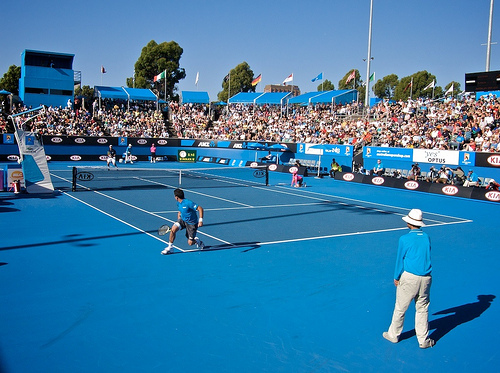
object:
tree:
[388, 70, 442, 107]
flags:
[308, 72, 325, 94]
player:
[103, 143, 118, 172]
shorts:
[105, 157, 116, 164]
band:
[405, 214, 423, 222]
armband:
[194, 216, 203, 224]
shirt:
[391, 229, 432, 283]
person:
[148, 140, 159, 164]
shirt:
[149, 145, 157, 153]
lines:
[180, 165, 472, 254]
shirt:
[175, 200, 201, 228]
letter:
[425, 157, 432, 164]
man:
[378, 206, 436, 349]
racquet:
[155, 223, 180, 238]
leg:
[166, 219, 184, 248]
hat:
[400, 205, 427, 227]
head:
[401, 208, 427, 229]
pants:
[386, 270, 433, 346]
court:
[0, 159, 499, 371]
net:
[68, 163, 270, 191]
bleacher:
[0, 49, 499, 205]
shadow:
[396, 294, 496, 345]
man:
[156, 187, 206, 255]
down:
[156, 219, 203, 255]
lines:
[54, 185, 187, 254]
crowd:
[0, 91, 499, 157]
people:
[472, 131, 483, 151]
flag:
[150, 67, 168, 102]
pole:
[161, 79, 170, 107]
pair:
[387, 270, 431, 343]